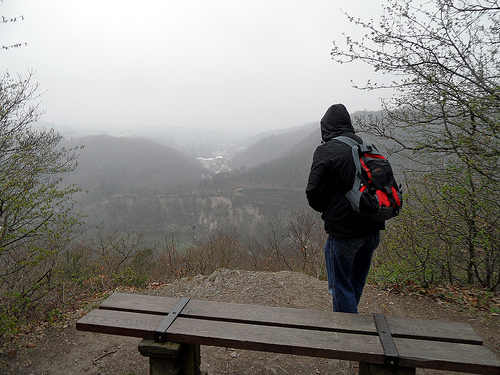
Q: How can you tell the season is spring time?
A: Buds on trees.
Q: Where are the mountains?
A: Background.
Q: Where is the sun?
A: Behind clouds.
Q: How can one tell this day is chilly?
A: Jacket with hoodie up.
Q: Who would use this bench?
A: Hikers.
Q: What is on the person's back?
A: Backpack.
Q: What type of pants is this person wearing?
A: Jeans.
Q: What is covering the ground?
A: Dirt, rocks and leaves.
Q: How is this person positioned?
A: Standing.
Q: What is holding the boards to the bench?
A: Metal straps and bolts.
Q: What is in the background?
A: Mountains and valley.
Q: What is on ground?
A: Leaves.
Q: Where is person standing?
A: On concrete slab.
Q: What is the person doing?
A: Overlooking the valley.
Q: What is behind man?
A: A wooden bench.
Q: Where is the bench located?
A: Behind person.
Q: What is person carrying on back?
A: Backpack.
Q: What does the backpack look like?
A: Black, grey, and red.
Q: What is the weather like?
A: Cloudy.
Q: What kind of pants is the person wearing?
A: Blue jeans.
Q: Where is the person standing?
A: On ledge.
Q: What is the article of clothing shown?
A: Black hoodie jacket.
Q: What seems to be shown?
A: A group of trees.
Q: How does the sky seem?
A: White and hazy.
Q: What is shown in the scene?
A: A large hillside with trees.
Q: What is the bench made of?
A: Wood.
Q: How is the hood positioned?
A: Up.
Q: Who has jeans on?
A: The person.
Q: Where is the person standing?
A: On a cliff.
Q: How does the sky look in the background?
A: Foggy.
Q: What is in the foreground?
A: Bench.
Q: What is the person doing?
A: Looking out at the mountains.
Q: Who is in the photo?
A: A man.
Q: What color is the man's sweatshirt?
A: Black.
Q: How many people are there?
A: One.